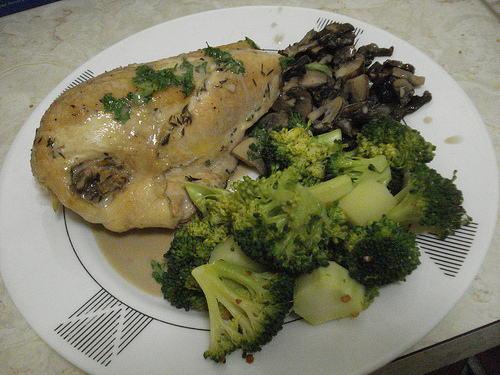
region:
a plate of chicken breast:
[33, 38, 268, 228]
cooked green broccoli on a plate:
[188, 144, 448, 362]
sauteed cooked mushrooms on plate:
[266, 13, 426, 153]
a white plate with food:
[42, 8, 499, 370]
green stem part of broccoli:
[188, 249, 255, 333]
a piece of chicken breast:
[58, 75, 240, 200]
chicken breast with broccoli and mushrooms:
[131, 43, 376, 230]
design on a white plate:
[37, 274, 157, 374]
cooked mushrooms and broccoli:
[273, 10, 425, 208]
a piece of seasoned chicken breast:
[41, 63, 253, 181]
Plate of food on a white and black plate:
[15, 4, 482, 362]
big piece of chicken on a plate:
[29, 8, 439, 365]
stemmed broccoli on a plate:
[47, 19, 449, 354]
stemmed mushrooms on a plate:
[298, 13, 435, 170]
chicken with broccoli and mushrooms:
[36, 22, 468, 344]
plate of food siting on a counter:
[7, 5, 492, 368]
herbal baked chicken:
[47, 33, 284, 222]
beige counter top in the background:
[4, 9, 498, 374]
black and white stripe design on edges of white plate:
[25, 41, 497, 367]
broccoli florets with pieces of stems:
[155, 112, 454, 372]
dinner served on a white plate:
[60, 30, 476, 342]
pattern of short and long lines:
[40, 281, 165, 361]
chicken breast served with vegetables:
[41, 35, 296, 230]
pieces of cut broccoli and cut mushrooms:
[166, 41, 456, 313]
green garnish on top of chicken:
[96, 36, 246, 121]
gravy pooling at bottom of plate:
[85, 215, 175, 292]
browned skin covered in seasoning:
[42, 50, 253, 215]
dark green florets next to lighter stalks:
[191, 136, 431, 321]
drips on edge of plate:
[261, 0, 291, 50]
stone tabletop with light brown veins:
[5, 0, 110, 97]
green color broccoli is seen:
[257, 187, 372, 269]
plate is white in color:
[21, 262, 111, 312]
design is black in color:
[70, 271, 140, 336]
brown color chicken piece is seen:
[61, 82, 266, 187]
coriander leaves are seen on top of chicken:
[101, 51, 221, 116]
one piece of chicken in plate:
[70, 65, 295, 190]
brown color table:
[17, 30, 103, 55]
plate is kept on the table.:
[60, 40, 155, 75]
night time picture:
[20, 25, 455, 345]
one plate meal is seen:
[27, 28, 444, 310]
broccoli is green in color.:
[222, 181, 387, 270]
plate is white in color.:
[36, 246, 208, 351]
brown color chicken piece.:
[68, 89, 245, 176]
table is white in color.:
[7, 23, 82, 59]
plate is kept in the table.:
[28, 39, 313, 136]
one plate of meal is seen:
[38, 47, 446, 286]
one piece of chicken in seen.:
[47, 61, 310, 203]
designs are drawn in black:
[48, 258, 163, 364]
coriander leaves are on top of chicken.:
[127, 56, 197, 111]